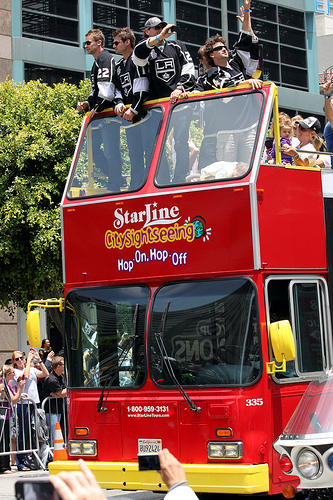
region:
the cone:
[45, 415, 71, 466]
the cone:
[38, 412, 83, 495]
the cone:
[44, 413, 57, 431]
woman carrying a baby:
[277, 112, 317, 160]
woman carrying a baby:
[263, 108, 324, 189]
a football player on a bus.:
[127, 7, 195, 101]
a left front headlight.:
[197, 425, 247, 466]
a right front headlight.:
[65, 423, 107, 459]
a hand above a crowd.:
[43, 454, 110, 498]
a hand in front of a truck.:
[149, 437, 208, 497]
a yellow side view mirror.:
[264, 310, 298, 381]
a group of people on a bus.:
[67, 13, 263, 119]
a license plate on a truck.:
[136, 429, 168, 459]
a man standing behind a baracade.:
[7, 335, 52, 438]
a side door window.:
[260, 260, 330, 385]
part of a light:
[221, 456, 227, 470]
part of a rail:
[33, 430, 49, 441]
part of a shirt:
[10, 392, 31, 421]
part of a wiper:
[179, 394, 182, 408]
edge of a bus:
[245, 437, 256, 447]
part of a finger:
[76, 476, 83, 484]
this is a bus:
[81, 121, 273, 345]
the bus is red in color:
[222, 403, 256, 420]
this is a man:
[202, 19, 251, 77]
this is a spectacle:
[210, 42, 232, 47]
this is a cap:
[144, 12, 164, 24]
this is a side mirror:
[265, 318, 295, 366]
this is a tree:
[17, 216, 59, 270]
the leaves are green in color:
[13, 117, 46, 160]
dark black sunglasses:
[14, 355, 24, 360]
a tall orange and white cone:
[52, 423, 72, 463]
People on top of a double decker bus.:
[70, 8, 330, 165]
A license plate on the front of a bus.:
[136, 438, 166, 454]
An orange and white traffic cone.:
[50, 422, 70, 465]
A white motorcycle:
[277, 361, 327, 498]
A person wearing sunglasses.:
[12, 342, 50, 442]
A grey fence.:
[1, 394, 60, 467]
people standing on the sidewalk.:
[2, 335, 84, 468]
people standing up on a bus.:
[75, 2, 271, 173]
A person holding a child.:
[282, 113, 321, 166]